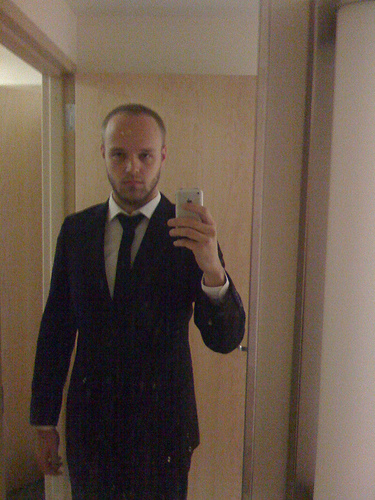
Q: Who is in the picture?
A: A man.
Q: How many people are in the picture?
A: One.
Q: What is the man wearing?
A: A suit.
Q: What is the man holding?
A: Phone.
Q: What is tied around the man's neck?
A: Tie.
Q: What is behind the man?
A: A door.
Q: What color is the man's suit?
A: Black.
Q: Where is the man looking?
A: In the mirror.